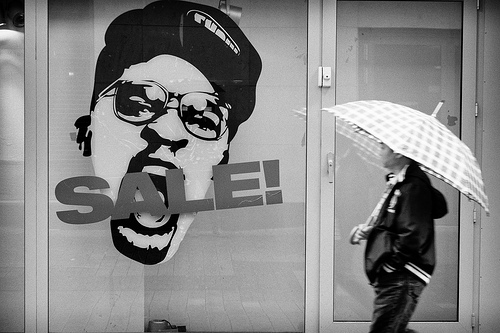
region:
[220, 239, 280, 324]
glass to the shop of a business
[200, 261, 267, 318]
reflection of the brick grounds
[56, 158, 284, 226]
a sale sign on the wall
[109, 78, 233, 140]
glasses for vision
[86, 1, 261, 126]
hat on head for style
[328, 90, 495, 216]
umbrella for blocking rain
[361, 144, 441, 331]
person walking down sidewalk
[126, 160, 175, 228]
mouth open indicating speech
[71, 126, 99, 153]
ears for listening and hearing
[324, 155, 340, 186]
door knob for opening door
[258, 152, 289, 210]
exclamation mark painted on window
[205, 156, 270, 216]
large letter painted on a window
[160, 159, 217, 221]
large letter painted on a window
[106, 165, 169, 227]
large letter painted on a window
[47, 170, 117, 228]
large letter painted on a window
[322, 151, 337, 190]
silver handle on a door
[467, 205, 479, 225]
metal hinge on a door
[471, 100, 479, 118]
metal hinge on a door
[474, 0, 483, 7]
metal hinge on a door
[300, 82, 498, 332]
person walking with an umbrella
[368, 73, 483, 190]
a large white umbrella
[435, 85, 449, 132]
the tip of an umbrella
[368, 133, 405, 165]
the face of a man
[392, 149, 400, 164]
the ear of a man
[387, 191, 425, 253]
the arm of a man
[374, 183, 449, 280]
the jacket of a man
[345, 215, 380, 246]
the hand of a man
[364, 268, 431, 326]
the pants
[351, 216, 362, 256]
the handle of an umbrella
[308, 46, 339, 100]
the hinge of a door